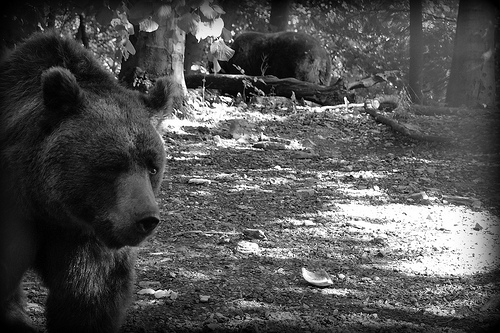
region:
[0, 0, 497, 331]
two grizzly bears foraging in the woods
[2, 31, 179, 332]
a bear walking through the forest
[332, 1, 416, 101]
thick trees past the bears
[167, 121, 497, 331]
a dirt ground in the forest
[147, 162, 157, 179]
the bears dark eyes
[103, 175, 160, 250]
the bears light muzzle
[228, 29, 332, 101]
a bear walking into the woods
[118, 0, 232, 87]
a large tree on the trail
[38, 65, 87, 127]
the bears large ears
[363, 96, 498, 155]
a broken tree root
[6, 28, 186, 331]
brown bear in foreground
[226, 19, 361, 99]
brown bear in background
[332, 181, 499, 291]
spot of sunlight on the ground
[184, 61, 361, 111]
fallen log in front of bear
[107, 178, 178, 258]
snout of foreground bear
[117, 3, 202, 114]
tree trunk behind foreground bear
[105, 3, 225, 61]
leaves in front of tree trunk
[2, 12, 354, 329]
two brown bears in the forest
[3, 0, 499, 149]
trees in the forest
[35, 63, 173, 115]
bear in the foreground's ears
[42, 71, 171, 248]
the face of a bear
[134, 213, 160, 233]
the nose of a bear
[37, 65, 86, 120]
the ear of a bear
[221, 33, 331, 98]
the backside of a bear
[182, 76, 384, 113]
a fallen tree in leaves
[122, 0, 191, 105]
the base of a tree trunk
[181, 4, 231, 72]
leaves on a tree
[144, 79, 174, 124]
the ear of a bear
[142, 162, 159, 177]
the eye of a bear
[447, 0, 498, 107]
the trunk of a tree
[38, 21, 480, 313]
the picture is black and white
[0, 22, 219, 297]
the bear is furry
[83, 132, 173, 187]
the eyes are open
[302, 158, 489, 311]
the sun is on the ground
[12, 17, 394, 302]
there are two bears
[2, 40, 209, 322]
the bear is looking ahead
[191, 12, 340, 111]
the bear is in the background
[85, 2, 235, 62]
leaves of a tree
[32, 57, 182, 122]
the bears ears are round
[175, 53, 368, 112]
a fallen tree on the ground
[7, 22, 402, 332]
The bears are in the forest.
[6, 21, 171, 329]
The bear is large.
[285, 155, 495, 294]
A white spot on the ground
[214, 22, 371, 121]
A bear deeper in the forest.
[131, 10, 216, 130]
The tree trunk is large.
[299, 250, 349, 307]
A scrap on the ground.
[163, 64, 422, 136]
The tree trunk is in front of the bear.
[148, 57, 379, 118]
The tree trunk is fallen.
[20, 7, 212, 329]
The bear is walking.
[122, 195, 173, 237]
The bear's nose is black.